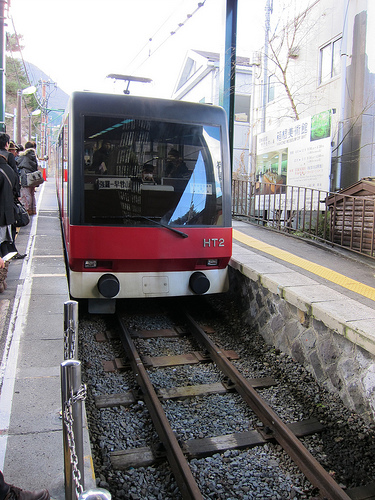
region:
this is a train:
[82, 166, 255, 340]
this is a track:
[162, 363, 265, 491]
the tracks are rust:
[142, 416, 189, 444]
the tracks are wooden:
[160, 450, 205, 494]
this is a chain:
[59, 437, 73, 451]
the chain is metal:
[57, 420, 84, 469]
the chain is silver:
[59, 457, 91, 472]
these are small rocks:
[121, 461, 156, 491]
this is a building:
[278, 198, 372, 254]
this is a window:
[273, 35, 371, 92]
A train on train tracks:
[51, 85, 371, 497]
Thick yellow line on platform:
[228, 221, 372, 303]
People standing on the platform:
[0, 126, 48, 270]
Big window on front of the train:
[79, 108, 225, 231]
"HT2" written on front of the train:
[197, 232, 229, 253]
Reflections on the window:
[83, 113, 223, 224]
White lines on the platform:
[0, 179, 65, 472]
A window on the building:
[316, 29, 346, 86]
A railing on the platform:
[232, 174, 373, 260]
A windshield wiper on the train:
[119, 208, 189, 241]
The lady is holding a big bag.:
[17, 141, 46, 203]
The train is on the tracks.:
[62, 94, 250, 374]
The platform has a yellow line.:
[232, 221, 326, 289]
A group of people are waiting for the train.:
[2, 131, 47, 266]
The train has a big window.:
[77, 99, 237, 245]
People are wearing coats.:
[0, 134, 44, 226]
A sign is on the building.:
[250, 107, 346, 218]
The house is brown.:
[324, 173, 373, 259]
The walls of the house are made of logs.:
[319, 175, 374, 247]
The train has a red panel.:
[69, 219, 242, 269]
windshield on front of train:
[79, 111, 224, 229]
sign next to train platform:
[252, 108, 333, 208]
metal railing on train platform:
[237, 175, 373, 239]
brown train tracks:
[86, 307, 319, 499]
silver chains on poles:
[61, 363, 85, 499]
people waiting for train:
[0, 132, 38, 261]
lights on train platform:
[13, 83, 35, 138]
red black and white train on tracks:
[50, 95, 232, 316]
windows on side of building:
[315, 33, 343, 86]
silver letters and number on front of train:
[202, 236, 225, 248]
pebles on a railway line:
[200, 455, 309, 497]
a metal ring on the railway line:
[59, 404, 79, 485]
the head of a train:
[67, 94, 240, 299]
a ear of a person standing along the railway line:
[6, 141, 9, 147]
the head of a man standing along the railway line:
[0, 132, 12, 151]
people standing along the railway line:
[2, 133, 42, 236]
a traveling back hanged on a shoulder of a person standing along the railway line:
[26, 171, 46, 187]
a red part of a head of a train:
[75, 233, 228, 271]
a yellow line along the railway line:
[286, 252, 342, 289]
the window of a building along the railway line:
[319, 42, 343, 83]